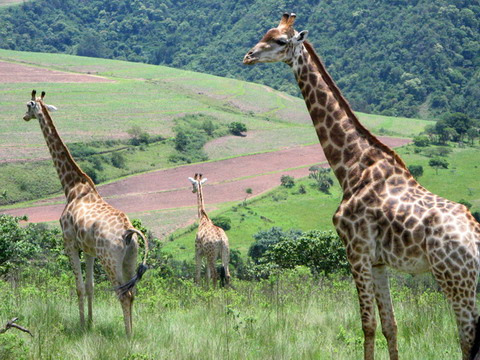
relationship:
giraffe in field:
[243, 12, 479, 359] [7, 0, 478, 357]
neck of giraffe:
[290, 55, 404, 203] [242, 8, 477, 357]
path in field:
[15, 146, 333, 228] [3, 50, 478, 358]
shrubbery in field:
[3, 212, 346, 306] [3, 50, 478, 358]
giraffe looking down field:
[175, 162, 253, 299] [3, 50, 478, 358]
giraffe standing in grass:
[18, 83, 181, 344] [9, 264, 474, 358]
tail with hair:
[119, 220, 153, 299] [118, 263, 155, 300]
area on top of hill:
[4, 56, 129, 94] [3, 47, 435, 182]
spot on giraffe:
[371, 190, 409, 230] [242, 8, 477, 357]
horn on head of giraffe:
[184, 168, 199, 189] [181, 165, 246, 308]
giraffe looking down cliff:
[187, 172, 230, 290] [2, 179, 478, 300]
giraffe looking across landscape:
[23, 89, 149, 336] [3, 47, 471, 358]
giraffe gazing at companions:
[242, 8, 477, 357] [15, 67, 278, 337]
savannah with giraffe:
[3, 2, 479, 356] [243, 12, 479, 359]